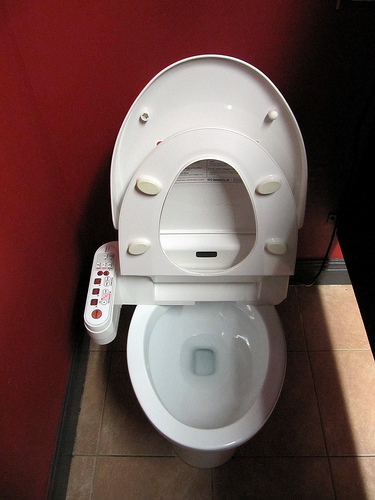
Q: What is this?
A: Toilet.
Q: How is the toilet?
A: Digital.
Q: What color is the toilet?
A: White.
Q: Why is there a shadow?
A: Light.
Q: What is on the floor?
A: Tiles.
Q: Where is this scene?
A: Toilet stall scene.